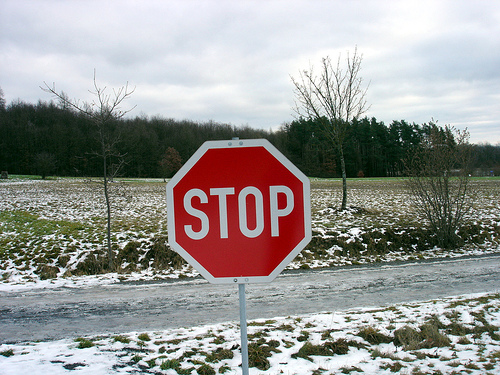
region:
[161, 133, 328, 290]
A red and white sign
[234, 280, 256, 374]
A pole holding the sign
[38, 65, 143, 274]
A tree whithout leaves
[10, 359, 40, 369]
Part of the white snow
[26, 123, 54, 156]
Part of the green trees in distance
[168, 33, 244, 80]
Part of the cloudy sky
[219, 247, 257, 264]
Part of the red and white sign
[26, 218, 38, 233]
Part of the green grass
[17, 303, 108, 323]
Part of the road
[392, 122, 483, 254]
A small tree near the road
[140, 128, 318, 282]
a red STOP sign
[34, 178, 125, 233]
grass covered with snow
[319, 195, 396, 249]
grass covered with snow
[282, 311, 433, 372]
grass covered with snow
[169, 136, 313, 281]
a red and white stop sign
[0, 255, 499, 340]
a road between two fields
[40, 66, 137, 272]
a tree with no leaves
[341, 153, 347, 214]
a skinny tree trunk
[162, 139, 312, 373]
an octagon shaped sign on a metal pole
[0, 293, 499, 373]
a snow covered field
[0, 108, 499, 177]
a stand of trees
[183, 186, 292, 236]
white letters on a red background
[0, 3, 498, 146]
an overcast sky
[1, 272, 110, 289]
a patch of snow alongside a road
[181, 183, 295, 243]
red lettering on a white sign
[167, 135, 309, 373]
a stop sign on a grey metal post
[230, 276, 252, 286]
grey bolts mounting the stop sign to the post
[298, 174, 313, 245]
white trim of the red stop sign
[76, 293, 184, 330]
grey gravel of the road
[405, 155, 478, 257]
a green plant growing next to the road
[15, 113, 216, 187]
trees growing on the edge of the field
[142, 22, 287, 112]
white cloudy skies over the field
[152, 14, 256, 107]
fluffy white clouds in the sky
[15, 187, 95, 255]
sparse snowy patches on the ground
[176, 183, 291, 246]
white lettering on the sign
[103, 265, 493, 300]
road is filled with ice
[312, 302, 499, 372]
grass has snow on it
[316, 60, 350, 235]
tree is bare no leaves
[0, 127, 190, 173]
trees in the distance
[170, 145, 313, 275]
sign is an octagon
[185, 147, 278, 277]
red in back of white lettering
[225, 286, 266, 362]
pole that sign is on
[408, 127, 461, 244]
bare tree on side of road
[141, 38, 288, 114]
clouds in the sky